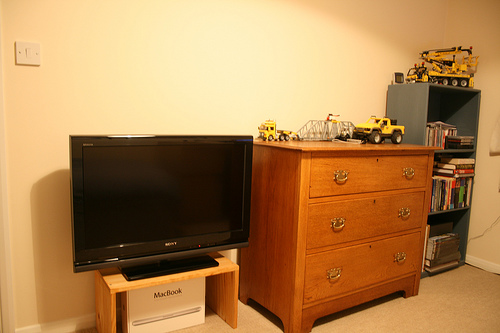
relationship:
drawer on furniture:
[302, 229, 424, 299] [237, 138, 427, 331]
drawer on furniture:
[308, 190, 425, 250] [237, 138, 427, 331]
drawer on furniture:
[303, 233, 421, 305] [237, 138, 427, 331]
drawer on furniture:
[310, 200, 428, 230] [237, 138, 427, 331]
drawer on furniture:
[320, 166, 430, 185] [239, 129, 442, 330]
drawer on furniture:
[309, 154, 429, 198] [239, 129, 442, 330]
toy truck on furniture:
[353, 115, 405, 145] [239, 129, 442, 330]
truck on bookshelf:
[406, 45, 479, 88] [386, 83, 476, 281]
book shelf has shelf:
[384, 84, 481, 278] [424, 247, 476, 270]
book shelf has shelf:
[384, 84, 481, 278] [425, 197, 475, 216]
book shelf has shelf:
[384, 84, 481, 278] [427, 140, 478, 155]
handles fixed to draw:
[321, 205, 413, 232] [300, 191, 437, 248]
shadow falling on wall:
[11, 149, 71, 309] [5, 5, 383, 107]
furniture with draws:
[254, 143, 438, 317] [309, 157, 423, 285]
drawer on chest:
[308, 190, 425, 250] [242, 138, 442, 329]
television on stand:
[71, 136, 254, 282] [93, 248, 272, 330]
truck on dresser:
[423, 40, 477, 87] [429, 79, 484, 272]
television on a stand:
[71, 136, 254, 282] [97, 267, 247, 329]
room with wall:
[14, 13, 481, 328] [1, 6, 442, 331]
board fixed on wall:
[6, 42, 38, 65] [69, 30, 116, 87]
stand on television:
[129, 253, 226, 279] [72, 127, 260, 261]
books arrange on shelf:
[431, 157, 475, 212] [428, 206, 470, 217]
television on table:
[72, 127, 260, 261] [105, 278, 127, 293]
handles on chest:
[334, 167, 368, 186] [292, 153, 441, 293]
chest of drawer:
[236, 140, 444, 332] [309, 154, 429, 198]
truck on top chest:
[254, 114, 284, 144] [236, 140, 444, 332]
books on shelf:
[432, 153, 478, 209] [415, 86, 432, 139]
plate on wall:
[15, 42, 44, 61] [54, 33, 101, 94]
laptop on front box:
[136, 290, 213, 328] [123, 289, 217, 331]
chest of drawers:
[242, 138, 442, 329] [301, 153, 429, 304]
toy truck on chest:
[350, 113, 407, 143] [242, 138, 442, 329]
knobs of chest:
[328, 164, 418, 183] [242, 138, 442, 329]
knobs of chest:
[328, 206, 410, 230] [242, 138, 442, 329]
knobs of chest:
[324, 249, 406, 283] [242, 138, 442, 329]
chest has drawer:
[242, 138, 442, 329] [309, 154, 434, 199]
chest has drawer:
[242, 138, 442, 329] [305, 190, 426, 250]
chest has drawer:
[242, 138, 442, 329] [299, 228, 423, 308]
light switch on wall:
[15, 39, 43, 66] [2, 6, 497, 328]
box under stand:
[122, 268, 214, 331] [95, 251, 251, 331]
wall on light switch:
[1, 6, 442, 331] [6, 34, 48, 69]